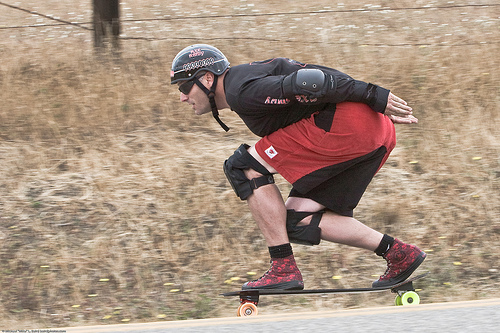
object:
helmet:
[170, 41, 232, 85]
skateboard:
[220, 270, 433, 319]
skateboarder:
[172, 44, 428, 290]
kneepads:
[221, 140, 258, 201]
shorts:
[248, 103, 395, 217]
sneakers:
[241, 238, 429, 290]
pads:
[289, 70, 333, 101]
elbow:
[280, 67, 339, 107]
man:
[169, 42, 427, 290]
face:
[177, 75, 212, 115]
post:
[86, 1, 126, 61]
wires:
[0, 0, 92, 43]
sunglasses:
[176, 71, 208, 93]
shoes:
[241, 238, 427, 291]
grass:
[30, 50, 148, 150]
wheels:
[238, 289, 420, 317]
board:
[223, 270, 428, 314]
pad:
[281, 218, 321, 247]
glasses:
[180, 73, 207, 95]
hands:
[353, 81, 419, 123]